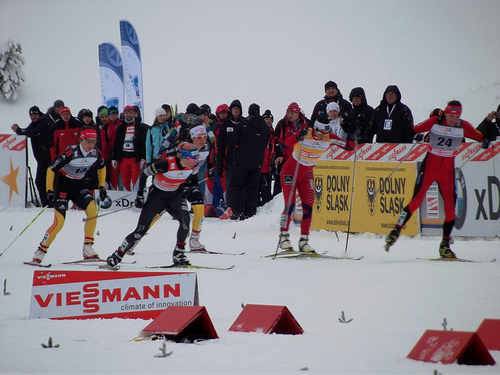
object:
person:
[385, 100, 491, 257]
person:
[279, 117, 357, 253]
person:
[146, 123, 209, 250]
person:
[107, 143, 199, 268]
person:
[32, 126, 107, 262]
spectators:
[11, 80, 500, 220]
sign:
[30, 270, 200, 319]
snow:
[0, 215, 498, 375]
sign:
[312, 160, 420, 236]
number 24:
[437, 137, 452, 147]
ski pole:
[345, 142, 357, 252]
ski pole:
[274, 140, 303, 254]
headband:
[80, 129, 97, 140]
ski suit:
[395, 117, 483, 236]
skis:
[417, 258, 497, 263]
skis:
[261, 251, 329, 258]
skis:
[186, 252, 245, 255]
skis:
[146, 264, 236, 270]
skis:
[22, 262, 51, 268]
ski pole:
[1, 205, 46, 256]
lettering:
[34, 282, 182, 313]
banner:
[120, 21, 144, 123]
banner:
[99, 43, 124, 118]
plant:
[41, 337, 59, 349]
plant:
[154, 343, 173, 357]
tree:
[1, 37, 27, 101]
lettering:
[326, 175, 407, 216]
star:
[0, 157, 19, 202]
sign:
[0, 134, 27, 209]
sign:
[141, 306, 219, 339]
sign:
[229, 304, 304, 334]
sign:
[408, 329, 495, 365]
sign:
[475, 319, 499, 350]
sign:
[96, 188, 136, 209]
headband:
[189, 125, 205, 138]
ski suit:
[40, 145, 108, 249]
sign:
[419, 141, 500, 236]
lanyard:
[387, 104, 396, 117]